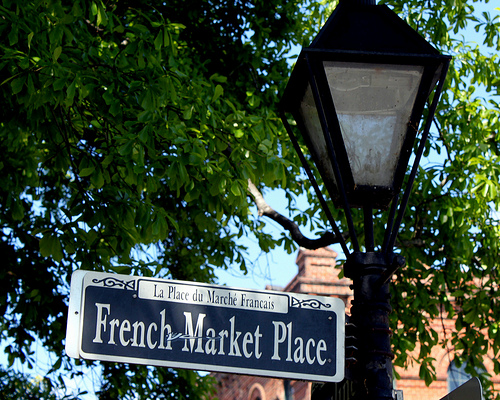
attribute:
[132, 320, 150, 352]
letter — white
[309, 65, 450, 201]
glass — frosted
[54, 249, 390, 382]
sign — black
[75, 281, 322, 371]
lettering — white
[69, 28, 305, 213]
tree — leafy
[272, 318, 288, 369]
letter — white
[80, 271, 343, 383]
signboard — white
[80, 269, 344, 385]
street sign — blue and white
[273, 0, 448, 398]
street light — black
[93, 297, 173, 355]
french — word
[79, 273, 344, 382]
sign — blue, white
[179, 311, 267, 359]
market — word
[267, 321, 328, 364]
place — word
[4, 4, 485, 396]
tree — green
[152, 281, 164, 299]
la — word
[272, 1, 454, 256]
light — off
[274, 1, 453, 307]
light — black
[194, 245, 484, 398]
building — red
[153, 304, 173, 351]
letter — white